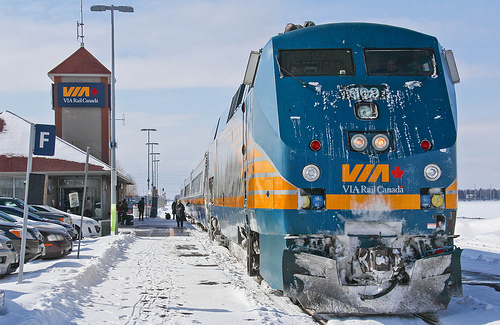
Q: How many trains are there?
A: One.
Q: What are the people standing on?
A: A sidewalk.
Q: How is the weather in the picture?
A: Cold and clear.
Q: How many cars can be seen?
A: 6.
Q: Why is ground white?
A: Snow.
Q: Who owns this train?
A: VIA Rail Canada.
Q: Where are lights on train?
A: Front.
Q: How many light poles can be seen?
A: 5.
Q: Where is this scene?
A: Train depot.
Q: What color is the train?
A: Blue and yellow.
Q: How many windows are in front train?
A: 2.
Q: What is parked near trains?
A: Cars.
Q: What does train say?
A: VIA rail canada.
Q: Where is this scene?
A: Canada.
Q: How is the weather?
A: Snowy.